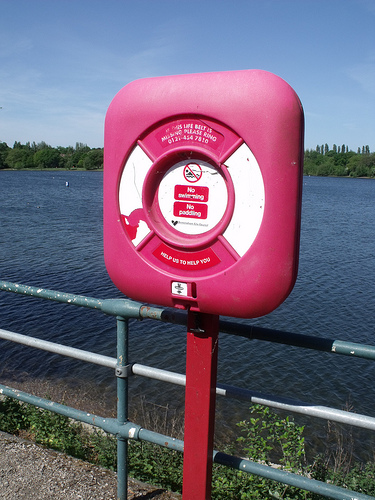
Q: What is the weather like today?
A: It is clear.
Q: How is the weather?
A: It is clear.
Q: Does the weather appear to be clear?
A: Yes, it is clear.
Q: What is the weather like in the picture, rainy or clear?
A: It is clear.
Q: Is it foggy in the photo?
A: No, it is clear.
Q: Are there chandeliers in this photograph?
A: No, there are no chandeliers.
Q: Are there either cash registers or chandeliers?
A: No, there are no chandeliers or cash registers.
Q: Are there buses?
A: No, there are no buses.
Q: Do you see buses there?
A: No, there are no buses.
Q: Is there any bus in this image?
A: No, there are no buses.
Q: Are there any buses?
A: No, there are no buses.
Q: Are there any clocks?
A: No, there are no clocks.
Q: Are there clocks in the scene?
A: No, there are no clocks.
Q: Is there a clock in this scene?
A: No, there are no clocks.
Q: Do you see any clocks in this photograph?
A: No, there are no clocks.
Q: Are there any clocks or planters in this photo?
A: No, there are no clocks or planters.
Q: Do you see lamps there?
A: No, there are no lamps.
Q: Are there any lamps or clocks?
A: No, there are no lamps or clocks.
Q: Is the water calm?
A: Yes, the water is calm.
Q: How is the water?
A: The water is calm.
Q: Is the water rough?
A: No, the water is calm.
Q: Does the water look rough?
A: No, the water is calm.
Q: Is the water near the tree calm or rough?
A: The water is calm.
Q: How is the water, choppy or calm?
A: The water is calm.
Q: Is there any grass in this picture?
A: Yes, there is grass.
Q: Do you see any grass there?
A: Yes, there is grass.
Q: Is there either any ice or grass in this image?
A: Yes, there is grass.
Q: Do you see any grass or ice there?
A: Yes, there is grass.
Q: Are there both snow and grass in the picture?
A: No, there is grass but no snow.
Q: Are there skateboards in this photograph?
A: No, there are no skateboards.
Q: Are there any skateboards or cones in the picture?
A: No, there are no skateboards or cones.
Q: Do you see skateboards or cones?
A: No, there are no skateboards or cones.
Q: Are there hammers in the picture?
A: No, there are no hammers.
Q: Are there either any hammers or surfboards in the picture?
A: No, there are no hammers or surfboards.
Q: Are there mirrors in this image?
A: No, there are no mirrors.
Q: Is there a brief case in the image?
A: No, there are no briefcases.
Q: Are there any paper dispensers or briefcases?
A: No, there are no briefcases or paper dispensers.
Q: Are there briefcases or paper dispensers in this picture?
A: No, there are no briefcases or paper dispensers.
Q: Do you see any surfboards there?
A: No, there are no surfboards.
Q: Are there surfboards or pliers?
A: No, there are no surfboards or pliers.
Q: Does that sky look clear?
A: Yes, the sky is clear.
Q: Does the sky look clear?
A: Yes, the sky is clear.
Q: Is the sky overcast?
A: No, the sky is clear.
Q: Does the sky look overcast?
A: No, the sky is clear.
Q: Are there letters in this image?
A: Yes, there are letters.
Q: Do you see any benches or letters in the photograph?
A: Yes, there are letters.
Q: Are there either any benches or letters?
A: Yes, there are letters.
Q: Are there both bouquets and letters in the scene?
A: No, there are letters but no bouquets.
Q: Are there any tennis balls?
A: No, there are no tennis balls.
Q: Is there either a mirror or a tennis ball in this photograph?
A: No, there are no tennis balls or mirrors.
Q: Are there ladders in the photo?
A: No, there are no ladders.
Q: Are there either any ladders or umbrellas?
A: No, there are no ladders or umbrellas.